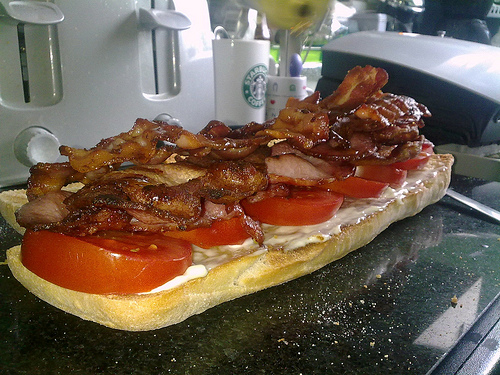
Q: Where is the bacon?
A: On top.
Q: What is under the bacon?
A: Tomato.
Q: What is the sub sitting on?
A: Counter.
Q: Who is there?
A: No one.